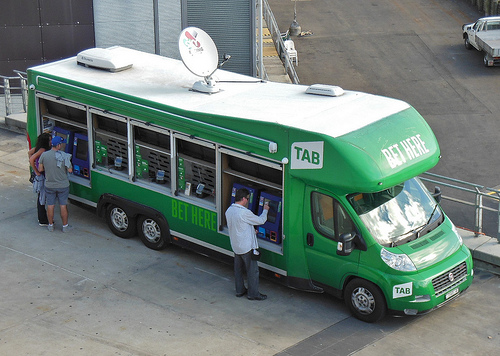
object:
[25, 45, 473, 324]
truck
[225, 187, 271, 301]
person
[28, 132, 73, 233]
people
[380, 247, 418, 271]
light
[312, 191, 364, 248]
window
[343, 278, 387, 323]
tire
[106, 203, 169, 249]
tires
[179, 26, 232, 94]
satelite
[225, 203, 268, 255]
shirt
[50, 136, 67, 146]
hat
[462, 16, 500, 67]
truck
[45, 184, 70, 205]
shorts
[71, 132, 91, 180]
machine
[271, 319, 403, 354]
line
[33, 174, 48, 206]
shirt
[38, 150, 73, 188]
shirt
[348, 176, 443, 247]
windshield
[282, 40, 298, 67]
chairs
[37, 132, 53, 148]
hair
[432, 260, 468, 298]
grill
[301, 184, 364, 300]
door